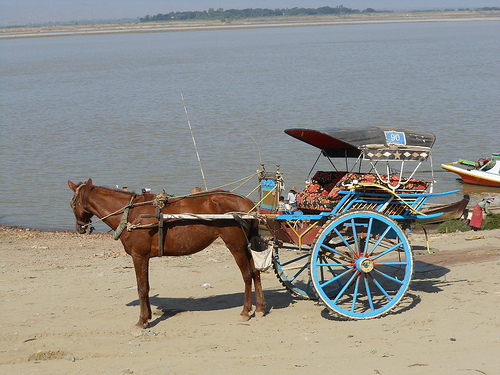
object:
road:
[0, 219, 500, 372]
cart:
[274, 123, 461, 319]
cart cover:
[280, 120, 446, 160]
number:
[382, 129, 407, 147]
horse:
[66, 171, 269, 337]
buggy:
[276, 118, 466, 319]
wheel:
[307, 209, 415, 322]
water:
[0, 19, 500, 234]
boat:
[437, 146, 499, 188]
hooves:
[130, 314, 156, 337]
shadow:
[117, 257, 455, 324]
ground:
[0, 218, 500, 374]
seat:
[292, 169, 431, 216]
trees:
[140, 6, 373, 25]